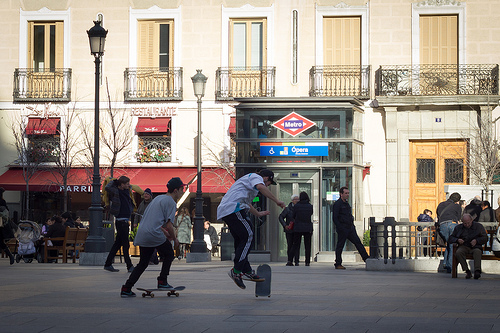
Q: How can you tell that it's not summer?
A: No leaves on trees.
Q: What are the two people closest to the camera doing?
A: Skateboarding.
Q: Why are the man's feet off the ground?
A: Doing a trick.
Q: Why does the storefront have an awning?
A: To keep the sun out.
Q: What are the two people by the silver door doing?
A: Talking.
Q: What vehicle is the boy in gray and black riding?
A: A skateboard.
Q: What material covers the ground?
A: Asphalt.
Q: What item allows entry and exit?
A: The door?.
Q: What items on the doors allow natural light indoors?
A: The windows.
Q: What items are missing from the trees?
A: Leaves.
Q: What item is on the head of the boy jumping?
A: A cap.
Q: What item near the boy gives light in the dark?
A: The street lamp.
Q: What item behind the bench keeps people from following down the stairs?
A: The fence.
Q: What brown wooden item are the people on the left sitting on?
A: A bench.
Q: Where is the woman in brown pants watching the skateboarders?
A: On the bench in front of the fence.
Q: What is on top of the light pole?
A: Light.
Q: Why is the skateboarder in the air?
A: Trick.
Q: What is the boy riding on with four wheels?
A: Skateboard.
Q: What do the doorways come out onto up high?
A: Balcony.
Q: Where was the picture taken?
A: A courtyard.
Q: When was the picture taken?
A: Daytime.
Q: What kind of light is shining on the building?
A: Sunlight.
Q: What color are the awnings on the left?
A: Red.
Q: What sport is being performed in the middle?
A: Skateboarding.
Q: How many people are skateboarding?
A: Two.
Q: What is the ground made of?
A: Brick.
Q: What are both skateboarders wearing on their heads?
A: Caps.